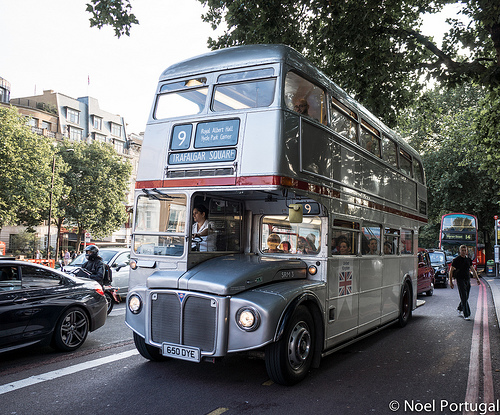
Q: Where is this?
A: This is at the road.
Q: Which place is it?
A: It is a road.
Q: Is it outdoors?
A: Yes, it is outdoors.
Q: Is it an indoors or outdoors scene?
A: It is outdoors.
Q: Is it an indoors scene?
A: No, it is outdoors.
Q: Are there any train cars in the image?
A: No, there are no train cars.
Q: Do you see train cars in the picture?
A: No, there are no train cars.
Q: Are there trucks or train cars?
A: No, there are no train cars or trucks.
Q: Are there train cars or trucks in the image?
A: No, there are no train cars or trucks.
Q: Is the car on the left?
A: Yes, the car is on the left of the image.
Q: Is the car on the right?
A: No, the car is on the left of the image.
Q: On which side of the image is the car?
A: The car is on the left of the image.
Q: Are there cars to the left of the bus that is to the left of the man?
A: Yes, there is a car to the left of the bus.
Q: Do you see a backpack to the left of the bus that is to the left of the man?
A: No, there is a car to the left of the bus.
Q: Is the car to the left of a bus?
A: Yes, the car is to the left of a bus.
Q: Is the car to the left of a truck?
A: No, the car is to the left of a bus.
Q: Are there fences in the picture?
A: No, there are no fences.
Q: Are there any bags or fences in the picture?
A: No, there are no fences or bags.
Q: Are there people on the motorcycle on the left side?
A: Yes, there is a person on the motorcycle.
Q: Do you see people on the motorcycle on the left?
A: Yes, there is a person on the motorcycle.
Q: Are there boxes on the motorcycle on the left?
A: No, there is a person on the motorcycle.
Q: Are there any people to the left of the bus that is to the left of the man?
A: Yes, there is a person to the left of the bus.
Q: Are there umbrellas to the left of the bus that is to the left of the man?
A: No, there is a person to the left of the bus.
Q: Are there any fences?
A: No, there are no fences.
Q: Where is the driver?
A: The driver is on the bus.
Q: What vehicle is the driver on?
A: The driver is on the bus.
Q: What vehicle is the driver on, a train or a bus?
A: The driver is on a bus.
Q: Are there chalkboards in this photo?
A: No, there are no chalkboards.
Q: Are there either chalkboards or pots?
A: No, there are no chalkboards or pots.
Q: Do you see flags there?
A: Yes, there is a flag.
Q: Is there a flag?
A: Yes, there is a flag.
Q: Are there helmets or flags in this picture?
A: Yes, there is a flag.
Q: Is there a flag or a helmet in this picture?
A: Yes, there is a flag.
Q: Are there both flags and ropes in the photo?
A: No, there is a flag but no ropes.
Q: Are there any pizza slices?
A: No, there are no pizza slices.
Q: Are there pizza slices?
A: No, there are no pizza slices.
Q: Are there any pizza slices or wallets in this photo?
A: No, there are no pizza slices or wallets.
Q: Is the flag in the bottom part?
A: Yes, the flag is in the bottom of the image.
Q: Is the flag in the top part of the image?
A: No, the flag is in the bottom of the image.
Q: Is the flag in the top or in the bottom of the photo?
A: The flag is in the bottom of the image.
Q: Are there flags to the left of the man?
A: Yes, there is a flag to the left of the man.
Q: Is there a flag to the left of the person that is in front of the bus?
A: Yes, there is a flag to the left of the man.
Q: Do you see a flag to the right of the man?
A: No, the flag is to the left of the man.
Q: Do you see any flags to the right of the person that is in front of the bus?
A: No, the flag is to the left of the man.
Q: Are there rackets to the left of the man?
A: No, there is a flag to the left of the man.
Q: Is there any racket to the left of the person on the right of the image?
A: No, there is a flag to the left of the man.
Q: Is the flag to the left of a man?
A: Yes, the flag is to the left of a man.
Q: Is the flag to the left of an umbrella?
A: No, the flag is to the left of a man.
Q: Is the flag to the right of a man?
A: No, the flag is to the left of a man.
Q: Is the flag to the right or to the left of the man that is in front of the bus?
A: The flag is to the left of the man.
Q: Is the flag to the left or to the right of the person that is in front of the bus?
A: The flag is to the left of the man.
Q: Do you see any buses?
A: Yes, there is a bus.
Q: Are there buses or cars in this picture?
A: Yes, there is a bus.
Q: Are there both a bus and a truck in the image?
A: No, there is a bus but no trucks.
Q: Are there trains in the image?
A: No, there are no trains.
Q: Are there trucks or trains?
A: No, there are no trains or trucks.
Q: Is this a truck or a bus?
A: This is a bus.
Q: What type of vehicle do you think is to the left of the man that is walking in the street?
A: The vehicle is a bus.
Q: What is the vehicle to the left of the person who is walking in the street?
A: The vehicle is a bus.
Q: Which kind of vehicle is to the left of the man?
A: The vehicle is a bus.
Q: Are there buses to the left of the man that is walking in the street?
A: Yes, there is a bus to the left of the man.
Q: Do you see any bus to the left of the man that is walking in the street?
A: Yes, there is a bus to the left of the man.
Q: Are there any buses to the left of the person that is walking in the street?
A: Yes, there is a bus to the left of the man.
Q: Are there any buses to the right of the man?
A: No, the bus is to the left of the man.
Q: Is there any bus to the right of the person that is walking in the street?
A: No, the bus is to the left of the man.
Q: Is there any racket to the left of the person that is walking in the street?
A: No, there is a bus to the left of the man.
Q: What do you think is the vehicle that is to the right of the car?
A: The vehicle is a bus.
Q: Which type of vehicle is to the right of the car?
A: The vehicle is a bus.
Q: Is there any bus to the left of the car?
A: No, the bus is to the right of the car.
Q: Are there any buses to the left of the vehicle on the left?
A: No, the bus is to the right of the car.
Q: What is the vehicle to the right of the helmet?
A: The vehicle is a bus.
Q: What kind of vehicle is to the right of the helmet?
A: The vehicle is a bus.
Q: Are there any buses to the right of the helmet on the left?
A: Yes, there is a bus to the right of the helmet.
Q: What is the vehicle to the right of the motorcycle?
A: The vehicle is a bus.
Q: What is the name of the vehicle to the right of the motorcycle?
A: The vehicle is a bus.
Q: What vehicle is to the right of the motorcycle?
A: The vehicle is a bus.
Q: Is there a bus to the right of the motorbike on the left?
A: Yes, there is a bus to the right of the motorcycle.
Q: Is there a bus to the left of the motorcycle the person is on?
A: No, the bus is to the right of the motorcycle.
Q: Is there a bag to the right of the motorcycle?
A: No, there is a bus to the right of the motorcycle.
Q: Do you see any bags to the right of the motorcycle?
A: No, there is a bus to the right of the motorcycle.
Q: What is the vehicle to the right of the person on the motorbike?
A: The vehicle is a bus.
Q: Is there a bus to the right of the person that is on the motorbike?
A: Yes, there is a bus to the right of the person.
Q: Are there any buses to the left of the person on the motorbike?
A: No, the bus is to the right of the person.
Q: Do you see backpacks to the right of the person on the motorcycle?
A: No, there is a bus to the right of the person.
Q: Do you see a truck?
A: No, there are no trucks.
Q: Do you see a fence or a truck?
A: No, there are no trucks or fences.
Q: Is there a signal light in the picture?
A: No, there are no traffic lights.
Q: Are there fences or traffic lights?
A: No, there are no traffic lights or fences.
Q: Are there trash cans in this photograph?
A: No, there are no trash cans.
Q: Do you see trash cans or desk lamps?
A: No, there are no trash cans or desk lamps.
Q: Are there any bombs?
A: No, there are no bombs.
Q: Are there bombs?
A: No, there are no bombs.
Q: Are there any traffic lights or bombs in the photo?
A: No, there are no bombs or traffic lights.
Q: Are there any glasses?
A: No, there are no glasses.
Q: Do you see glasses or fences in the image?
A: No, there are no glasses or fences.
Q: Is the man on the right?
A: Yes, the man is on the right of the image.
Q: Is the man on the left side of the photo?
A: No, the man is on the right of the image.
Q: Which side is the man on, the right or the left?
A: The man is on the right of the image.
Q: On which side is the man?
A: The man is on the right of the image.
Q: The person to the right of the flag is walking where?
A: The man is walking in the street.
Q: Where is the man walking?
A: The man is walking in the street.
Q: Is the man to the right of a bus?
A: Yes, the man is to the right of a bus.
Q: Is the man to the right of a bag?
A: No, the man is to the right of a bus.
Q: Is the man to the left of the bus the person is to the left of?
A: No, the man is to the right of the bus.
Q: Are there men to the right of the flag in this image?
A: Yes, there is a man to the right of the flag.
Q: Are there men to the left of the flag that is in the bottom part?
A: No, the man is to the right of the flag.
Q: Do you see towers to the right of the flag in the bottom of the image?
A: No, there is a man to the right of the flag.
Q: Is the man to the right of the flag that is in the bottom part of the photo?
A: Yes, the man is to the right of the flag.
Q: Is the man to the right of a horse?
A: No, the man is to the right of the flag.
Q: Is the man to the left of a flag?
A: No, the man is to the right of a flag.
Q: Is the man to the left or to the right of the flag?
A: The man is to the right of the flag.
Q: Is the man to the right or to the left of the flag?
A: The man is to the right of the flag.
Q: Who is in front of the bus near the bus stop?
A: The man is in front of the bus.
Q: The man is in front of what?
A: The man is in front of the bus.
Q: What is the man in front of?
A: The man is in front of the bus.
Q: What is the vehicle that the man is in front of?
A: The vehicle is a bus.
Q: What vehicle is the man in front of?
A: The man is in front of the bus.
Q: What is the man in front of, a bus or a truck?
A: The man is in front of a bus.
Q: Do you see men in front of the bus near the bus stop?
A: Yes, there is a man in front of the bus.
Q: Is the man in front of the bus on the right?
A: Yes, the man is in front of the bus.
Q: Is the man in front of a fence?
A: No, the man is in front of the bus.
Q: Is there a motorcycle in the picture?
A: Yes, there is a motorcycle.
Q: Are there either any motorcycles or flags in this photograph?
A: Yes, there is a motorcycle.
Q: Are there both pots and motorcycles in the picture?
A: No, there is a motorcycle but no pots.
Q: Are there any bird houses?
A: No, there are no bird houses.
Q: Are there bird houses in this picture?
A: No, there are no bird houses.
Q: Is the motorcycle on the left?
A: Yes, the motorcycle is on the left of the image.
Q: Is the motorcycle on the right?
A: No, the motorcycle is on the left of the image.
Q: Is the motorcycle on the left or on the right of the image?
A: The motorcycle is on the left of the image.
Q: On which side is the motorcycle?
A: The motorcycle is on the left of the image.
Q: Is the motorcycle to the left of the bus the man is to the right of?
A: Yes, the motorcycle is to the left of the bus.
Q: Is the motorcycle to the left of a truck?
A: No, the motorcycle is to the left of the bus.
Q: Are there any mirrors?
A: Yes, there is a mirror.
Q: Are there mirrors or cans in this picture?
A: Yes, there is a mirror.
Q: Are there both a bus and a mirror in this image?
A: Yes, there are both a mirror and a bus.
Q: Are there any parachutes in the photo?
A: No, there are no parachutes.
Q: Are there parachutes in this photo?
A: No, there are no parachutes.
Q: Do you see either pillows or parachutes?
A: No, there are no parachutes or pillows.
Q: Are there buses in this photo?
A: Yes, there is a bus.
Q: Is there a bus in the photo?
A: Yes, there is a bus.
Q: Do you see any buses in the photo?
A: Yes, there is a bus.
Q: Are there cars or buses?
A: Yes, there is a bus.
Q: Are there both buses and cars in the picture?
A: Yes, there are both a bus and a car.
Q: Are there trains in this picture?
A: No, there are no trains.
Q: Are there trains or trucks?
A: No, there are no trains or trucks.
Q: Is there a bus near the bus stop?
A: Yes, there is a bus near the bus stop.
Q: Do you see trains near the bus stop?
A: No, there is a bus near the bus stop.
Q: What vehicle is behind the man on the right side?
A: The vehicle is a bus.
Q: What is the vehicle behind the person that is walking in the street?
A: The vehicle is a bus.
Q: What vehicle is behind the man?
A: The vehicle is a bus.